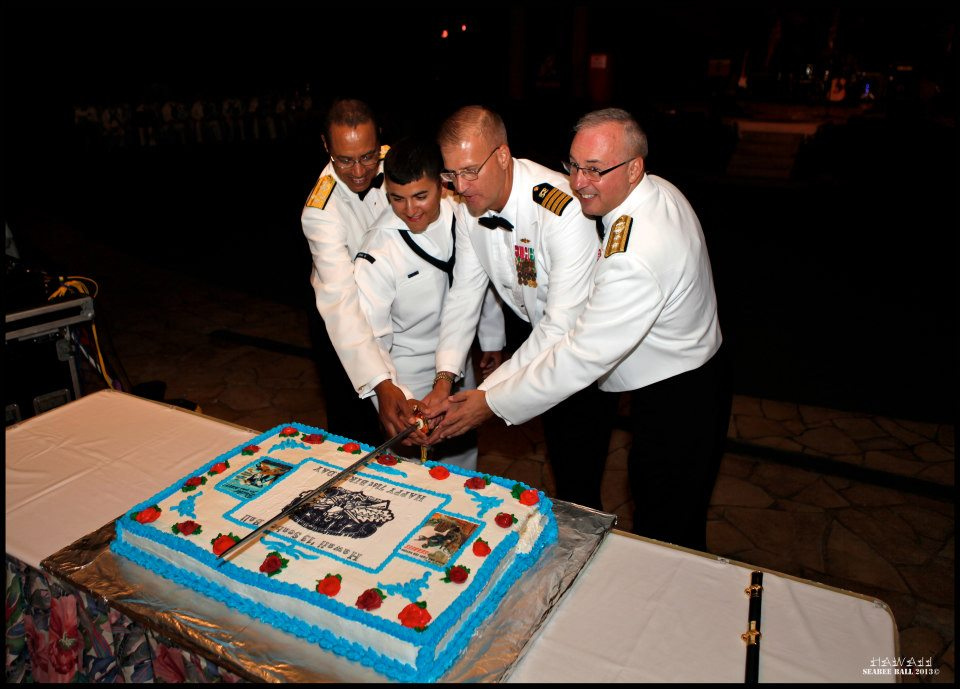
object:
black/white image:
[288, 485, 394, 538]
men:
[306, 98, 736, 555]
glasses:
[563, 160, 637, 181]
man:
[414, 104, 613, 510]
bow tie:
[479, 215, 514, 232]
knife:
[219, 418, 426, 562]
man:
[298, 99, 418, 462]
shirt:
[298, 144, 388, 399]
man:
[352, 143, 507, 469]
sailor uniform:
[352, 194, 480, 471]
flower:
[397, 600, 431, 632]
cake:
[109, 421, 562, 684]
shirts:
[354, 193, 508, 412]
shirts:
[436, 155, 604, 377]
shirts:
[476, 173, 726, 427]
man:
[436, 108, 734, 550]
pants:
[626, 341, 735, 553]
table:
[0, 386, 898, 686]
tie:
[397, 211, 458, 289]